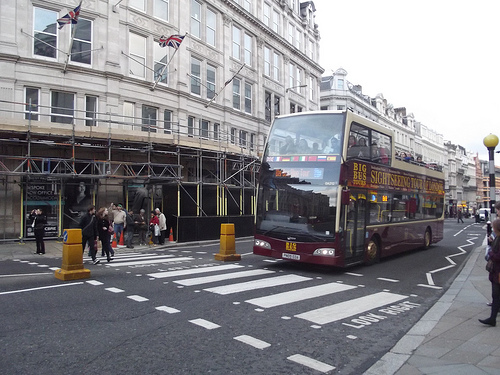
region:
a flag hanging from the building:
[151, 30, 195, 55]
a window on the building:
[33, 5, 58, 57]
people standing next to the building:
[13, 197, 194, 270]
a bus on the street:
[257, 108, 445, 260]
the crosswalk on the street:
[104, 225, 401, 355]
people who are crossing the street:
[76, 204, 132, 251]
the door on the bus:
[348, 196, 366, 248]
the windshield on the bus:
[262, 175, 338, 242]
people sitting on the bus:
[276, 135, 327, 149]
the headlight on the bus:
[311, 243, 338, 255]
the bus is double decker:
[254, 112, 445, 272]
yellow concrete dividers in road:
[57, 221, 242, 278]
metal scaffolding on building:
[0, 104, 265, 245]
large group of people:
[80, 201, 167, 261]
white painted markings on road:
[4, 225, 489, 374]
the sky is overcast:
[316, 0, 498, 165]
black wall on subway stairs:
[163, 214, 253, 244]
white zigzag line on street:
[418, 231, 483, 289]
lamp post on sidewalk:
[477, 130, 499, 328]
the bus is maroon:
[254, 108, 444, 268]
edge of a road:
[304, 319, 314, 339]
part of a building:
[163, 173, 173, 188]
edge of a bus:
[348, 181, 355, 194]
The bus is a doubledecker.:
[246, 86, 460, 273]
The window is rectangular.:
[13, 76, 44, 123]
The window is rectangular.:
[46, 83, 80, 127]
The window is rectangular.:
[81, 83, 103, 130]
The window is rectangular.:
[26, 0, 63, 60]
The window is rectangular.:
[63, 3, 99, 74]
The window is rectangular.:
[123, 18, 152, 85]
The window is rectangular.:
[149, 28, 176, 92]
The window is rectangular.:
[182, 37, 206, 100]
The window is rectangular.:
[201, 50, 222, 105]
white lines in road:
[3, 216, 484, 373]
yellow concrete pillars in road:
[55, 222, 240, 282]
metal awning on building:
[1, 102, 266, 247]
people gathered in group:
[74, 200, 168, 265]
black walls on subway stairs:
[162, 212, 256, 242]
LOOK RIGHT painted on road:
[338, 297, 422, 332]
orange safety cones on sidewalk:
[109, 227, 177, 247]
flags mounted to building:
[55, 0, 245, 113]